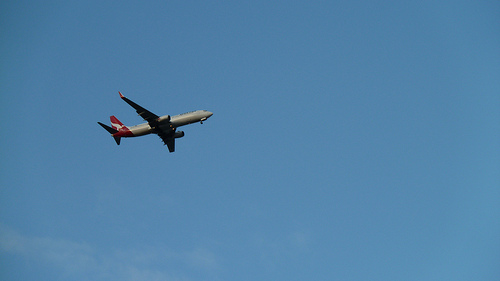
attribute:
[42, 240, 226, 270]
clouds — white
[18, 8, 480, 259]
sky — blue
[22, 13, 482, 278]
sky — blue, clear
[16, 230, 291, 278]
clouds — wispy, white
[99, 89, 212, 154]
plane — silver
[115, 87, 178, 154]
wings — red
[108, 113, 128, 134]
tail — red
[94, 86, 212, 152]
plane — silver, large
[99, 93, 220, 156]
plane — silver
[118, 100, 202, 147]
underbelly — dark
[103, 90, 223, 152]
plane — silver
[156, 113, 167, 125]
engine — silver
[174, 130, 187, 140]
engine — silver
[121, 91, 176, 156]
wings — red